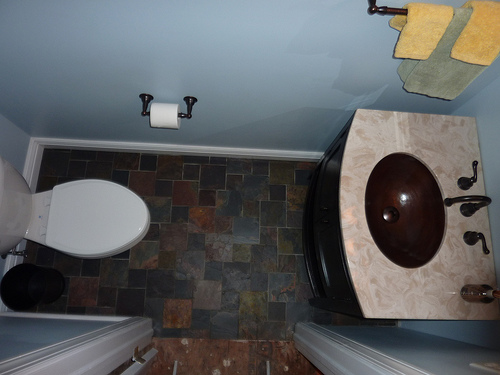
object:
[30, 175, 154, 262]
toilet bowl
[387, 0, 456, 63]
towel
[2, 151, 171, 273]
toilet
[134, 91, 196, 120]
holder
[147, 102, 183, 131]
toilet paper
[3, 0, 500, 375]
bathroom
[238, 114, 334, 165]
ground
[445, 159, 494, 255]
facets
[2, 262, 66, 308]
paper basket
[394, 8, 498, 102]
green towel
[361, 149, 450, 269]
sink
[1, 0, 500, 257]
wall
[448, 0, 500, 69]
towel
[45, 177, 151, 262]
lid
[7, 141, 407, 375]
flooring